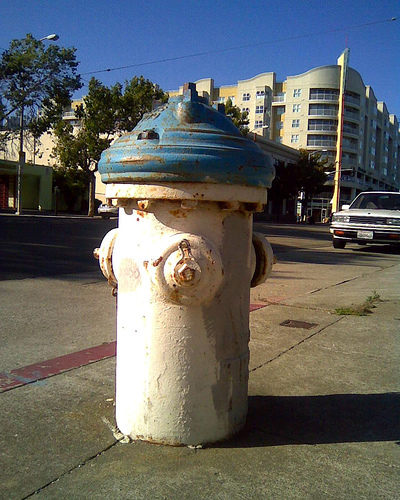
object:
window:
[290, 87, 300, 95]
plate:
[353, 229, 377, 241]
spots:
[151, 254, 164, 267]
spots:
[142, 258, 148, 271]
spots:
[210, 258, 216, 266]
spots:
[208, 246, 213, 254]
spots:
[134, 216, 142, 224]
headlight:
[388, 217, 399, 223]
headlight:
[333, 215, 349, 221]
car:
[98, 202, 118, 218]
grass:
[327, 290, 380, 316]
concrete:
[0, 221, 399, 499]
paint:
[111, 429, 173, 442]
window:
[289, 102, 302, 113]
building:
[1, 47, 398, 227]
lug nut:
[178, 264, 195, 284]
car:
[329, 189, 398, 255]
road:
[275, 230, 348, 285]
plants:
[313, 241, 390, 365]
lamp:
[14, 32, 62, 216]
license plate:
[356, 228, 373, 240]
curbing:
[326, 49, 350, 232]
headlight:
[329, 228, 352, 241]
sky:
[1, 2, 397, 123]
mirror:
[335, 199, 348, 211]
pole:
[12, 52, 25, 214]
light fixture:
[36, 30, 59, 44]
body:
[94, 90, 277, 449]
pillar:
[330, 189, 338, 201]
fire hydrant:
[95, 82, 281, 449]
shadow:
[205, 390, 397, 448]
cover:
[280, 317, 317, 326]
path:
[1, 222, 399, 499]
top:
[97, 83, 281, 199]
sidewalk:
[2, 223, 399, 497]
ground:
[3, 207, 397, 497]